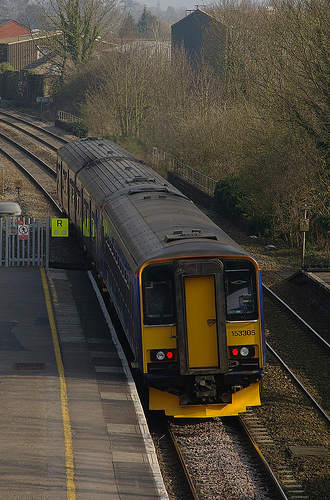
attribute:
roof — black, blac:
[87, 147, 195, 260]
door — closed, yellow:
[172, 261, 237, 396]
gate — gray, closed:
[8, 213, 55, 270]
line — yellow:
[36, 336, 90, 468]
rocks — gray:
[194, 437, 257, 497]